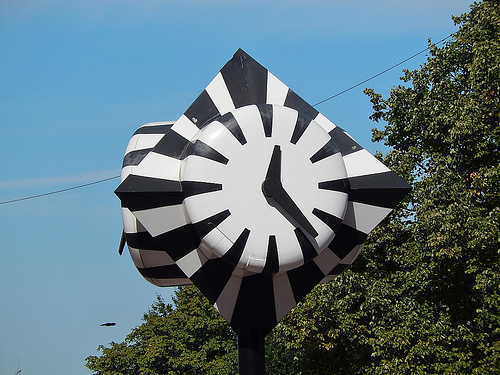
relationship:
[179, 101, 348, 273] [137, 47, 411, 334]
clock has stripes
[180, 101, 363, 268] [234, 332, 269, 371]
clock face on a pole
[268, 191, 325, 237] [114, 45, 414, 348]
minute hand of a clock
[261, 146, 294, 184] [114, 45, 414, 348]
hour hand of clock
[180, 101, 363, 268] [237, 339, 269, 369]
clock face on pole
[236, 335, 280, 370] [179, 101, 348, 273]
pole holding clock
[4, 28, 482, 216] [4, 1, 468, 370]
telephone line against sky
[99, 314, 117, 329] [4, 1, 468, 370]
bird flying sky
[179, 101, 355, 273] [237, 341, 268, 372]
clock on a pole